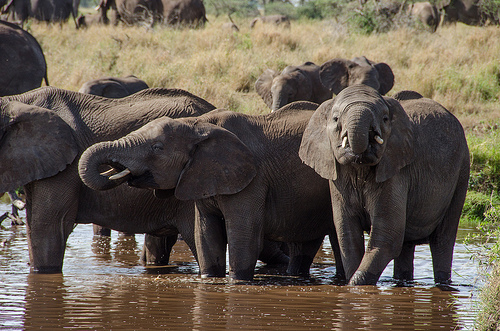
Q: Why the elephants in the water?
A: To drink and bath.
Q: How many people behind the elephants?
A: Zero.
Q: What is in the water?
A: Elephants.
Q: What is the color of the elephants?
A: Gray.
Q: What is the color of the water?
A: Brown.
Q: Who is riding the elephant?
A: No one.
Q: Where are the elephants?
A: In the water.